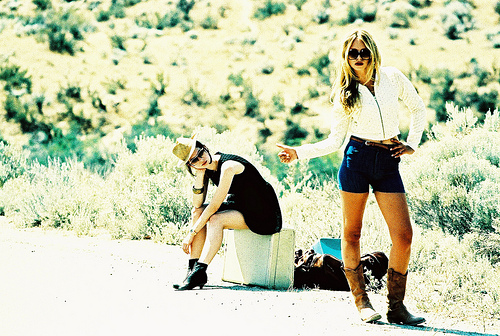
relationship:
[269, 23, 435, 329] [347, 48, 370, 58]
lady has sunglasses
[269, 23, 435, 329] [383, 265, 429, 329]
lady has boot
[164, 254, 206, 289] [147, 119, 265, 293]
booties of woman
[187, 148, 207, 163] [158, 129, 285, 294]
sunglasses of girl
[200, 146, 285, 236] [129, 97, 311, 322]
black dress of woman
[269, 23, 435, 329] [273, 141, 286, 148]
lady with her thumb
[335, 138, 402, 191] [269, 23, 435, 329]
shorts on lady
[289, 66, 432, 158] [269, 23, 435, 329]
shirt on lady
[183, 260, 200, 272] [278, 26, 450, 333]
boot on girl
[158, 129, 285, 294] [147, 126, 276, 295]
girl in dress hat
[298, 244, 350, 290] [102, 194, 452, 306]
bag on ground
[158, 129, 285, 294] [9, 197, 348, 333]
girl on road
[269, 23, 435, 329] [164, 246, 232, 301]
lady wearing boots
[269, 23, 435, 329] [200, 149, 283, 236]
lady wearing black dress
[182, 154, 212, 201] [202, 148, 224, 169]
right hand behind neck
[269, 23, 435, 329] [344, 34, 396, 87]
lady has hair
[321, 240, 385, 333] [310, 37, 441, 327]
foot of woman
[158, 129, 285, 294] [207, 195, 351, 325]
girl on bag